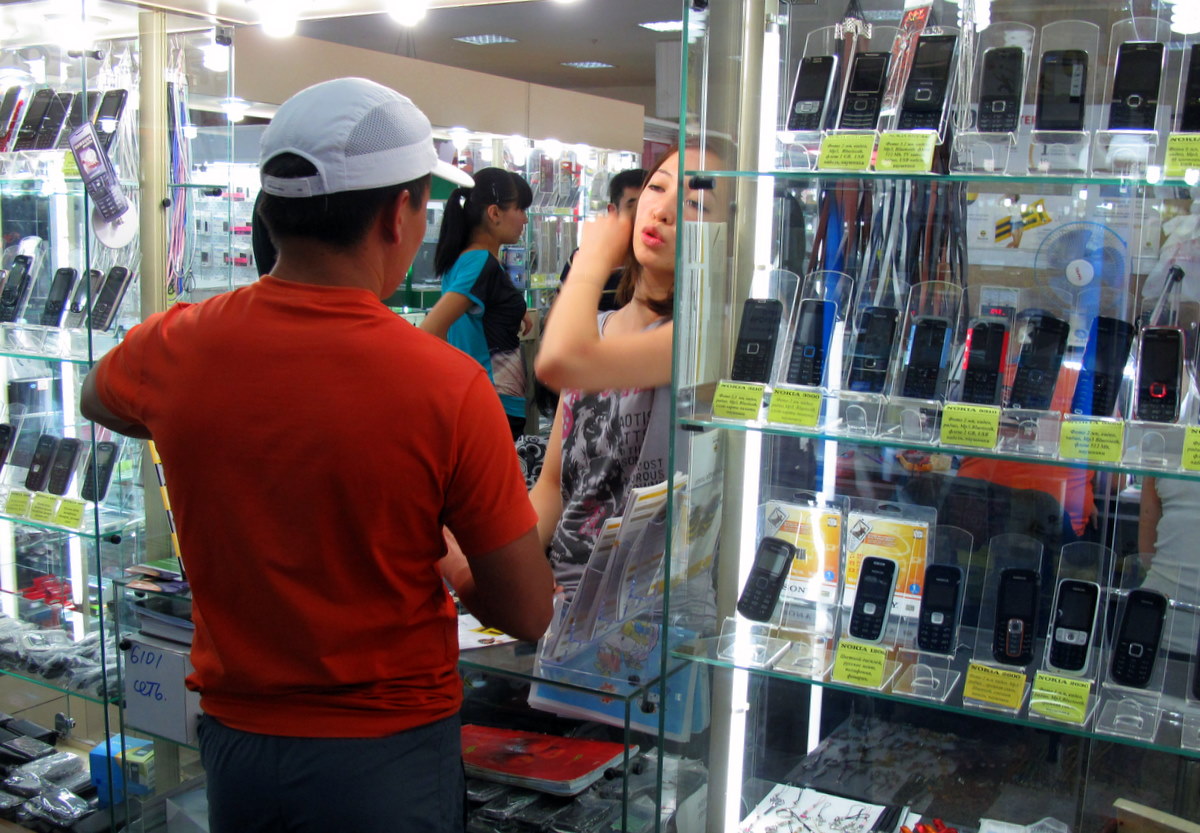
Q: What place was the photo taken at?
A: It was taken at the store.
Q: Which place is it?
A: It is a store.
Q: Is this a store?
A: Yes, it is a store.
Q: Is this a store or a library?
A: It is a store.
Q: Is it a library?
A: No, it is a store.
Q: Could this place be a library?
A: No, it is a store.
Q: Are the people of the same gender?
A: No, they are both male and female.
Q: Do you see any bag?
A: No, there are no bags.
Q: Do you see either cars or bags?
A: No, there are no bags or cars.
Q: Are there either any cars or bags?
A: No, there are no bags or cars.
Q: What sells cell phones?
A: The store sells cell phones.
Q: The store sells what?
A: The store sells cell phones.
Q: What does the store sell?
A: The store sells cell phones.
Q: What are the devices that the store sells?
A: The devices are cell phones.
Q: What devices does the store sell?
A: The store sells cell phones.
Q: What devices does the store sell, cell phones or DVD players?
A: The store sells cell phones.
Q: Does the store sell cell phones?
A: Yes, the store sells cell phones.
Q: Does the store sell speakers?
A: No, the store sells cell phones.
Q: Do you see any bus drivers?
A: No, there are no bus drivers.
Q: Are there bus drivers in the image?
A: No, there are no bus drivers.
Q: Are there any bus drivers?
A: No, there are no bus drivers.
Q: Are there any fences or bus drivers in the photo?
A: No, there are no bus drivers or fences.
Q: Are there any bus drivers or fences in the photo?
A: No, there are no bus drivers or fences.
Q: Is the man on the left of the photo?
A: Yes, the man is on the left of the image.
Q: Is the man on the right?
A: No, the man is on the left of the image.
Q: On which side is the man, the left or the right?
A: The man is on the left of the image.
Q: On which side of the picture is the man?
A: The man is on the left of the image.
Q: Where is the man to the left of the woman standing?
A: The man is standing in the store.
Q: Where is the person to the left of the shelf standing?
A: The man is standing in the store.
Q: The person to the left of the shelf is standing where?
A: The man is standing in the store.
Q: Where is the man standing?
A: The man is standing in the store.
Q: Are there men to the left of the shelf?
A: Yes, there is a man to the left of the shelf.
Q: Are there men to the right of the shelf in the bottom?
A: No, the man is to the left of the shelf.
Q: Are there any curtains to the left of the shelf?
A: No, there is a man to the left of the shelf.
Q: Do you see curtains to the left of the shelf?
A: No, there is a man to the left of the shelf.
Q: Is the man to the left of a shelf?
A: Yes, the man is to the left of a shelf.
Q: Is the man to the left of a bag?
A: No, the man is to the left of a shelf.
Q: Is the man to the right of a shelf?
A: No, the man is to the left of a shelf.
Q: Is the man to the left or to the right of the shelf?
A: The man is to the left of the shelf.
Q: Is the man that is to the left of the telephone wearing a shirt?
A: Yes, the man is wearing a shirt.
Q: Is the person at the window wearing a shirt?
A: Yes, the man is wearing a shirt.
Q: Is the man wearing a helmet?
A: No, the man is wearing a shirt.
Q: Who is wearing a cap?
A: The man is wearing a cap.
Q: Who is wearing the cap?
A: The man is wearing a cap.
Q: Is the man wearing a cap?
A: Yes, the man is wearing a cap.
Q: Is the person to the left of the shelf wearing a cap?
A: Yes, the man is wearing a cap.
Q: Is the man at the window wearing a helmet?
A: No, the man is wearing a cap.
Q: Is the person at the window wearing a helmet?
A: No, the man is wearing a cap.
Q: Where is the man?
A: The man is at the window.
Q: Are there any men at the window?
A: Yes, there is a man at the window.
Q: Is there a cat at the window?
A: No, there is a man at the window.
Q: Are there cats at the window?
A: No, there is a man at the window.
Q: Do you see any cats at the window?
A: No, there is a man at the window.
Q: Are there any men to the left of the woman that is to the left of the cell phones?
A: Yes, there is a man to the left of the woman.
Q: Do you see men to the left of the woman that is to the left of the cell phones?
A: Yes, there is a man to the left of the woman.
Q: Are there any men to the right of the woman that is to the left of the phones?
A: No, the man is to the left of the woman.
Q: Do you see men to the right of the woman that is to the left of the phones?
A: No, the man is to the left of the woman.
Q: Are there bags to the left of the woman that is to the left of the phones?
A: No, there is a man to the left of the woman.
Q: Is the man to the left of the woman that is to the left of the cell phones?
A: Yes, the man is to the left of the woman.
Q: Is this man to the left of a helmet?
A: No, the man is to the left of the woman.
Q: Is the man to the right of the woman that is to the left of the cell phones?
A: No, the man is to the left of the woman.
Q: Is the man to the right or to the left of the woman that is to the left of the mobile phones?
A: The man is to the left of the woman.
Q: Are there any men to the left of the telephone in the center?
A: Yes, there is a man to the left of the telephone.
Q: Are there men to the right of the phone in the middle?
A: No, the man is to the left of the telephone.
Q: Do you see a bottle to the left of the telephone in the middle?
A: No, there is a man to the left of the phone.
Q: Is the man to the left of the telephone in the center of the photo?
A: Yes, the man is to the left of the telephone.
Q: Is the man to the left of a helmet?
A: No, the man is to the left of the telephone.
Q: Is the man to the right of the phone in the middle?
A: No, the man is to the left of the telephone.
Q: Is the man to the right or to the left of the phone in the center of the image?
A: The man is to the left of the telephone.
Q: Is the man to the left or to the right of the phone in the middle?
A: The man is to the left of the telephone.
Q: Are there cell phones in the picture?
A: Yes, there are cell phones.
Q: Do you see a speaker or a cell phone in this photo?
A: Yes, there are cell phones.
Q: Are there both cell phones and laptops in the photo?
A: No, there are cell phones but no laptops.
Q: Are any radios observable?
A: No, there are no radios.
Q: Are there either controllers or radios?
A: No, there are no radios or controllers.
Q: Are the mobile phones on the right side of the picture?
A: Yes, the mobile phones are on the right of the image.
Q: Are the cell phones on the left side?
A: No, the cell phones are on the right of the image.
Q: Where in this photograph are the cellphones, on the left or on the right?
A: The cellphones are on the right of the image.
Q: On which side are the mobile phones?
A: The mobile phones are on the right of the image.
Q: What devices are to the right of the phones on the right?
A: The devices are cell phones.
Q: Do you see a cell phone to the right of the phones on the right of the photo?
A: Yes, there are cell phones to the right of the phones.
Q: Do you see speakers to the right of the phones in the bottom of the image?
A: No, there are cell phones to the right of the phones.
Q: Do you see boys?
A: No, there are no boys.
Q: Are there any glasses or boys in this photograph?
A: No, there are no boys or glasses.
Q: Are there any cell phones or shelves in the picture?
A: Yes, there are cell phones.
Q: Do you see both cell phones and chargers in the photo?
A: No, there are cell phones but no chargers.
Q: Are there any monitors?
A: No, there are no monitors.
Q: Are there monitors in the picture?
A: No, there are no monitors.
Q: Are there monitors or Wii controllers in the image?
A: No, there are no monitors or Wii controllers.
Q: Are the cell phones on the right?
A: Yes, the cell phones are on the right of the image.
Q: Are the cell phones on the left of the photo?
A: No, the cell phones are on the right of the image.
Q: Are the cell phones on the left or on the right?
A: The cell phones are on the right of the image.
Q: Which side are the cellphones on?
A: The cellphones are on the right of the image.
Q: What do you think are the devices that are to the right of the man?
A: The devices are cell phones.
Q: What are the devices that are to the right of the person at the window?
A: The devices are cell phones.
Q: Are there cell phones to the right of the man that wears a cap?
A: Yes, there are cell phones to the right of the man.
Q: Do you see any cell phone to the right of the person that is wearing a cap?
A: Yes, there are cell phones to the right of the man.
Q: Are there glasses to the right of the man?
A: No, there are cell phones to the right of the man.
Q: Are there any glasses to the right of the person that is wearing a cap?
A: No, there are cell phones to the right of the man.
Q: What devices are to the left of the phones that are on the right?
A: The devices are cell phones.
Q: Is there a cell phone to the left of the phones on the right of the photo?
A: Yes, there are cell phones to the left of the phones.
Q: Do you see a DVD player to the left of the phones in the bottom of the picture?
A: No, there are cell phones to the left of the phones.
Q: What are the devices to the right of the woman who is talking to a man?
A: The devices are cell phones.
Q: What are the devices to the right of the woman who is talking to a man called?
A: The devices are cell phones.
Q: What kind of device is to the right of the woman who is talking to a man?
A: The devices are cell phones.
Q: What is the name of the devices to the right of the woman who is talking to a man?
A: The devices are cell phones.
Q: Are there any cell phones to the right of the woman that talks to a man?
A: Yes, there are cell phones to the right of the woman.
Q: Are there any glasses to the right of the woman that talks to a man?
A: No, there are cell phones to the right of the woman.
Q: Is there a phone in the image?
A: Yes, there is a phone.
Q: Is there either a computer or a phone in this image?
A: Yes, there is a phone.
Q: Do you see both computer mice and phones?
A: No, there is a phone but no computer mice.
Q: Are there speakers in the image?
A: No, there are no speakers.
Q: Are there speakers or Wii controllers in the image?
A: No, there are no speakers or Wii controllers.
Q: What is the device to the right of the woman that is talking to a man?
A: The device is a phone.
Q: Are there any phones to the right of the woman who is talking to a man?
A: Yes, there is a phone to the right of the woman.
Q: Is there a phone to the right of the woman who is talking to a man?
A: Yes, there is a phone to the right of the woman.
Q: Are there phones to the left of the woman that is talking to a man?
A: No, the phone is to the right of the woman.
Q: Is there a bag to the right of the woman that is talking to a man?
A: No, there is a phone to the right of the woman.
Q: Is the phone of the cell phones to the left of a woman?
A: No, the phone is to the right of a woman.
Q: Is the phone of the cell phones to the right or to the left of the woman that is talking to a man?
A: The phone is to the right of the woman.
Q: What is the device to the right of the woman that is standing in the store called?
A: The device is a phone.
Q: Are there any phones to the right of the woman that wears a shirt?
A: Yes, there is a phone to the right of the woman.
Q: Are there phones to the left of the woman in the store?
A: No, the phone is to the right of the woman.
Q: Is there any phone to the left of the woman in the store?
A: No, the phone is to the right of the woman.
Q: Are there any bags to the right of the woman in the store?
A: No, there is a phone to the right of the woman.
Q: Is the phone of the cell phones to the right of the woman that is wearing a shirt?
A: Yes, the telephone is to the right of the woman.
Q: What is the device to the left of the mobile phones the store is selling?
A: The device is a phone.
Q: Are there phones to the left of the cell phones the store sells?
A: Yes, there is a phone to the left of the cellphones.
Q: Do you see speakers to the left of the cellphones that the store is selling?
A: No, there is a phone to the left of the mobile phones.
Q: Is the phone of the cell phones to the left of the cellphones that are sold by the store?
A: Yes, the telephone is to the left of the mobile phones.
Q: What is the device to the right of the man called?
A: The device is a phone.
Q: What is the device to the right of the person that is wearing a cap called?
A: The device is a phone.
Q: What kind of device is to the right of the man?
A: The device is a phone.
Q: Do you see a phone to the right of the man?
A: Yes, there is a phone to the right of the man.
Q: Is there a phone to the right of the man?
A: Yes, there is a phone to the right of the man.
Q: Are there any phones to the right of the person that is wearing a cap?
A: Yes, there is a phone to the right of the man.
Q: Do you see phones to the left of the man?
A: No, the phone is to the right of the man.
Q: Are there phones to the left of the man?
A: No, the phone is to the right of the man.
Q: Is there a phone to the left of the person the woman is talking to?
A: No, the phone is to the right of the man.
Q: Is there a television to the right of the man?
A: No, there is a phone to the right of the man.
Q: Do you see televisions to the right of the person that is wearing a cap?
A: No, there is a phone to the right of the man.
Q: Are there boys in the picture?
A: No, there are no boys.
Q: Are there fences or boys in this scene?
A: No, there are no boys or fences.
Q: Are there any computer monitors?
A: No, there are no computer monitors.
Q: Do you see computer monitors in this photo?
A: No, there are no computer monitors.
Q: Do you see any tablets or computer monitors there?
A: No, there are no computer monitors or tablets.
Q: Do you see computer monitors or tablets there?
A: No, there are no computer monitors or tablets.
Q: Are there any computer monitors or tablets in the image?
A: No, there are no computer monitors or tablets.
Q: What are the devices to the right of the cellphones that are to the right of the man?
A: The devices are phones.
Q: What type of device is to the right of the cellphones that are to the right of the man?
A: The devices are phones.